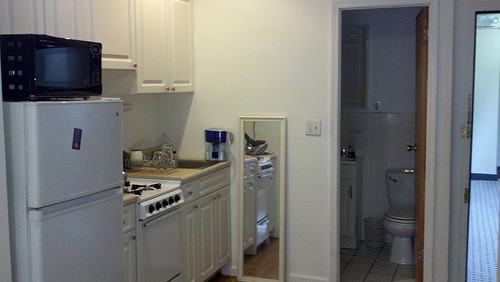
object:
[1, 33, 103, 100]
microwave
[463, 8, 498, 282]
mirror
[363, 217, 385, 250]
wastebasket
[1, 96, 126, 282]
refrigerator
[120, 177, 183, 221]
stove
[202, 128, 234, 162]
pitcher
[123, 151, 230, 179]
counter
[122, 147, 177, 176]
rack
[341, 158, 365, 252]
cabinet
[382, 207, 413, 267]
toilet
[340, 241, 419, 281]
floor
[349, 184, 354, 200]
knob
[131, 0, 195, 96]
cabinet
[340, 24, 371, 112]
mirror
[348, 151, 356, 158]
sink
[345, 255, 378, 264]
tile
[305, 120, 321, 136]
light switch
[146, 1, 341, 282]
wall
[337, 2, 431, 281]
bathroom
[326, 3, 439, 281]
doorway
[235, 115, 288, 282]
mirror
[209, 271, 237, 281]
floor